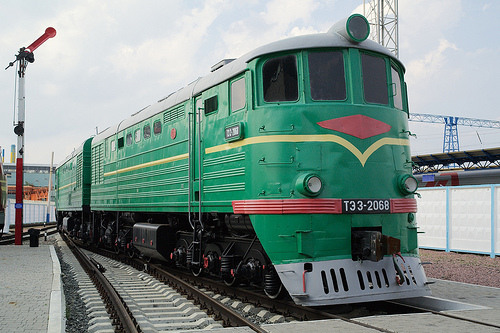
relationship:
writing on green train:
[344, 200, 394, 212] [54, 14, 435, 308]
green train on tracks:
[53, 17, 428, 307] [58, 237, 278, 332]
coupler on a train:
[348, 219, 405, 261] [60, 16, 424, 328]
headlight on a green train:
[301, 173, 325, 198] [54, 14, 435, 308]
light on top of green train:
[345, 12, 368, 39] [54, 14, 435, 308]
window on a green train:
[310, 50, 345, 100] [54, 14, 435, 308]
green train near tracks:
[54, 14, 435, 308] [59, 277, 208, 327]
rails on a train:
[169, 93, 220, 183] [94, 51, 495, 288]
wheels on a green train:
[167, 235, 287, 300] [54, 14, 435, 308]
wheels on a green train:
[70, 218, 135, 257] [54, 14, 435, 308]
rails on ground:
[53, 227, 498, 332] [419, 250, 499, 285]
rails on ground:
[53, 227, 498, 332] [64, 257, 76, 331]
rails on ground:
[53, 227, 498, 332] [232, 297, 283, 322]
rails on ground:
[53, 227, 498, 332] [41, 232, 56, 245]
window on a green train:
[262, 54, 300, 103] [54, 14, 435, 308]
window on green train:
[308, 50, 347, 102] [54, 14, 435, 308]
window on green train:
[389, 65, 402, 110] [54, 14, 435, 308]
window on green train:
[262, 54, 300, 103] [54, 14, 435, 308]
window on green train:
[359, 50, 387, 104] [54, 14, 435, 308]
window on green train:
[135, 128, 140, 142] [54, 14, 435, 308]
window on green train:
[204, 95, 219, 115] [54, 14, 435, 308]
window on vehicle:
[200, 87, 223, 117] [34, 37, 432, 322]